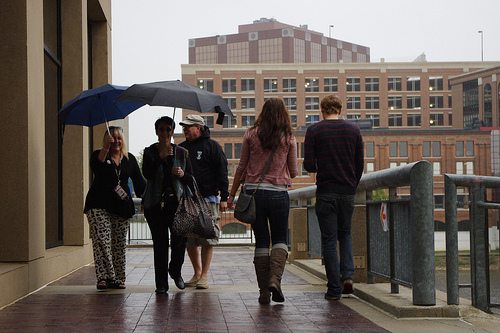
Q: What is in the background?
A: Building.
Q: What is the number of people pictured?
A: 5.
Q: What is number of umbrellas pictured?
A: 2.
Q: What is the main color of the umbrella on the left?
A: Blue.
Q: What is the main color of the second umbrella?
A: Black.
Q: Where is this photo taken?
A: City.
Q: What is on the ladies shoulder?
A: Bag.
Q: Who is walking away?
A: Man and woman.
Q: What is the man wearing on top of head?
A: Grey cap.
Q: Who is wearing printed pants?
A: Woman on far left.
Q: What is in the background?
A: Buildings.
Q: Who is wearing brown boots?
A: Woman walking away.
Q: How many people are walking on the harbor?
A: 5.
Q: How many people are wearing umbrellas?
A: 2.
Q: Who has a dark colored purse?
A: Woman walking away.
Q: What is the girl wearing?
A: Blue jeans.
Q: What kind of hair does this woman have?
A: Blonde.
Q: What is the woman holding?
A: An umbrella.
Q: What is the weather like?
A: Rain.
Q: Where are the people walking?
A: On the sidewalk.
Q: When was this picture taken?
A: Daytime.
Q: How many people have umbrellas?
A: Two.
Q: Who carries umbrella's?
A: The two women.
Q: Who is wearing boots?
A: The woman walking away.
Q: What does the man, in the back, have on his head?
A: A hat.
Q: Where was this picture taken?
A: The city.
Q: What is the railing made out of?
A: Metal.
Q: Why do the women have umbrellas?
A: To protect them from rain.